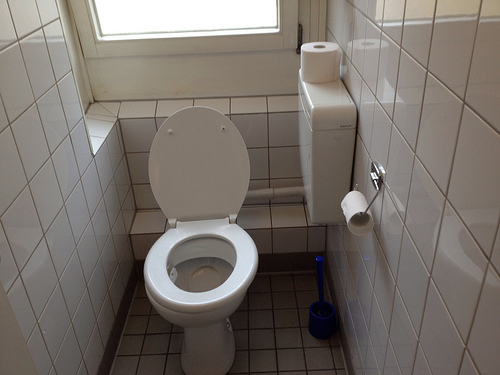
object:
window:
[90, 0, 276, 36]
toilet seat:
[141, 218, 261, 312]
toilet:
[142, 106, 260, 373]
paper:
[341, 190, 373, 235]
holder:
[351, 160, 383, 215]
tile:
[411, 69, 465, 199]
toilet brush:
[306, 256, 337, 339]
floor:
[112, 266, 350, 373]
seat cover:
[147, 107, 249, 227]